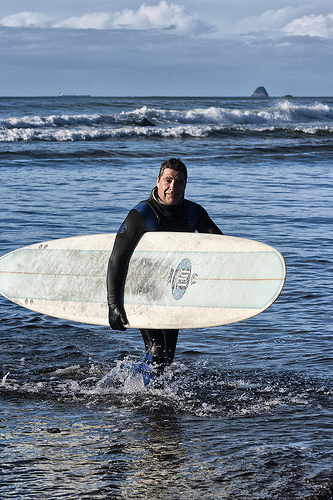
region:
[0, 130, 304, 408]
One man in the photo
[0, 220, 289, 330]
Surfboard in the man's hand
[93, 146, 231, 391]
Man wearing a wet suit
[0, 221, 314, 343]
Surfboard is white and blue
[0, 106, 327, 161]
Breaking waves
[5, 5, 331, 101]
Blue sky with clouds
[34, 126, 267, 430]
Man walking out of the water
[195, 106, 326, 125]
White caps on the waves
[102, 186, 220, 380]
The wet suit is black with blue accents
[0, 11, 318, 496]
Photo taken during the day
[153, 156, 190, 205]
the head of a person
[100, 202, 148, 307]
the arm of a person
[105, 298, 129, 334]
the hand of a person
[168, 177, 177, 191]
the nose of a person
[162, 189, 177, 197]
the mouth of a person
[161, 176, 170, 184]
the eye of a person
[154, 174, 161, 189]
the ear of a person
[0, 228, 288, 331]
a white and blue surfboard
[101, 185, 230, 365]
a black and blue wet suit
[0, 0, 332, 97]
a cloudy sky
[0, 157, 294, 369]
man carrying surfboard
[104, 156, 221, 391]
man wearing black and blue wetsuit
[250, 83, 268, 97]
tall island in the distance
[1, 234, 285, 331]
white and blue surfboard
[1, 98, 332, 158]
waves in the ocean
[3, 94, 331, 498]
deep blue color of the ocean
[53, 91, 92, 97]
long ship on the horizon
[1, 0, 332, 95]
dark and cloudy sky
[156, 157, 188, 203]
man with brown hair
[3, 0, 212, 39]
fluffy white cloud in the sky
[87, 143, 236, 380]
male surfer in diving suit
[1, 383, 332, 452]
blue water with splashing waves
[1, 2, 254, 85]
partly cloudy sky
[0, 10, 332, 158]
series of waves coming in to shore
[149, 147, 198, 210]
man with water in background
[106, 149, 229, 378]
wetsuit and gloves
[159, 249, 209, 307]
logo for surfboard company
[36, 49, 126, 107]
distant ship on open waters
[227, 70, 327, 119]
distant mountain on remote island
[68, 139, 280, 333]
person in the water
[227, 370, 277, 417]
water beneath the person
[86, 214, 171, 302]
arm of the man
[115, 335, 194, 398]
legs of the man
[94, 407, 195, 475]
reflection in the water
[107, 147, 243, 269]
man looking at the camera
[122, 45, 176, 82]
sky above the land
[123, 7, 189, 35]
clouds in the sky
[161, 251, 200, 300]
design on the board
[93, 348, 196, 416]
splashing water below the man